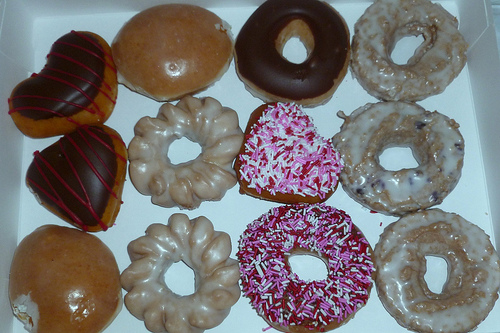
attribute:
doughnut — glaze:
[9, 223, 122, 331]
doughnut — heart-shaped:
[22, 119, 136, 234]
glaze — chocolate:
[22, 127, 112, 227]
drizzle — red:
[24, 129, 131, 225]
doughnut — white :
[120, 104, 252, 200]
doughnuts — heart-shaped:
[237, 114, 341, 196]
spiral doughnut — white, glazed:
[119, 211, 241, 331]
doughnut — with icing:
[333, 99, 466, 213]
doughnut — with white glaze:
[239, 87, 499, 217]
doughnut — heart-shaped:
[237, 101, 337, 206]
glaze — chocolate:
[18, 31, 102, 119]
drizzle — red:
[7, 29, 117, 129]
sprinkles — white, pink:
[249, 113, 330, 196]